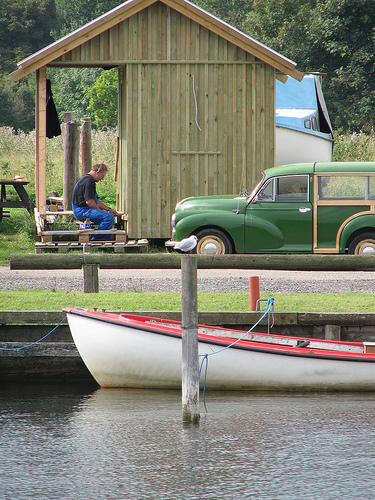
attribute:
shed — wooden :
[9, 2, 305, 259]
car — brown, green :
[163, 155, 371, 275]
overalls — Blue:
[65, 172, 116, 235]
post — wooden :
[178, 250, 206, 426]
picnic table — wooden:
[0, 175, 37, 218]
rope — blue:
[189, 290, 282, 360]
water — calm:
[4, 383, 372, 497]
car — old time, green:
[167, 161, 374, 255]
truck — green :
[163, 148, 372, 263]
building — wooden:
[8, 0, 306, 250]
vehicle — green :
[171, 159, 374, 257]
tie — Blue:
[201, 303, 274, 356]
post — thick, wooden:
[173, 246, 208, 431]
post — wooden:
[28, 80, 73, 227]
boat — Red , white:
[61, 304, 373, 388]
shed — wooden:
[49, 16, 274, 225]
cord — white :
[192, 72, 202, 133]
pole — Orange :
[248, 275, 260, 310]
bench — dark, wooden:
[0, 173, 35, 227]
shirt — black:
[68, 172, 98, 208]